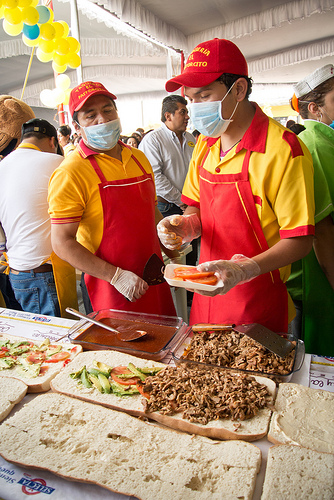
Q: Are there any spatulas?
A: Yes, there is a spatula.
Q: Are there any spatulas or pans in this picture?
A: Yes, there is a spatula.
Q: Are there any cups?
A: No, there are no cups.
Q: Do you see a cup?
A: No, there are no cups.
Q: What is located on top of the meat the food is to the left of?
A: The spatula is on top of the meat.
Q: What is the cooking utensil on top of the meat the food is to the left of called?
A: The cooking utensil is a spatula.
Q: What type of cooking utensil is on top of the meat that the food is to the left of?
A: The cooking utensil is a spatula.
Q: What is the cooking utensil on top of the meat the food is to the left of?
A: The cooking utensil is a spatula.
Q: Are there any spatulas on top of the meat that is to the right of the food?
A: Yes, there is a spatula on top of the meat.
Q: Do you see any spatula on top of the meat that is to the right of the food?
A: Yes, there is a spatula on top of the meat.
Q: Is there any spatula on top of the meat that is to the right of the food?
A: Yes, there is a spatula on top of the meat.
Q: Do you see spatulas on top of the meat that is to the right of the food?
A: Yes, there is a spatula on top of the meat.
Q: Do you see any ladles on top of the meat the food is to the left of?
A: No, there is a spatula on top of the meat.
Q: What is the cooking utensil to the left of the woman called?
A: The cooking utensil is a spatula.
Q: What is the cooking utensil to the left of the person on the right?
A: The cooking utensil is a spatula.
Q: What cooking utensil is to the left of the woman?
A: The cooking utensil is a spatula.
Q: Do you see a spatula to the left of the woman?
A: Yes, there is a spatula to the left of the woman.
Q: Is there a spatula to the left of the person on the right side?
A: Yes, there is a spatula to the left of the woman.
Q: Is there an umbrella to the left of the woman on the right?
A: No, there is a spatula to the left of the woman.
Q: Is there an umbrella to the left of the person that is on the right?
A: No, there is a spatula to the left of the woman.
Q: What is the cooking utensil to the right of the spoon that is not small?
A: The cooking utensil is a spatula.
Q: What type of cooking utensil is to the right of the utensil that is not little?
A: The cooking utensil is a spatula.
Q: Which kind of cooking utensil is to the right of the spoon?
A: The cooking utensil is a spatula.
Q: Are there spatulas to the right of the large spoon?
A: Yes, there is a spatula to the right of the spoon.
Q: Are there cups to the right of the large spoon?
A: No, there is a spatula to the right of the spoon.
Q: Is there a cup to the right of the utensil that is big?
A: No, there is a spatula to the right of the spoon.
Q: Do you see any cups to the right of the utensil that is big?
A: No, there is a spatula to the right of the spoon.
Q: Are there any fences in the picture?
A: No, there are no fences.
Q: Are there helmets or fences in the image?
A: No, there are no fences or helmets.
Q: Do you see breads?
A: Yes, there is a bread.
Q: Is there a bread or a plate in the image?
A: Yes, there is a bread.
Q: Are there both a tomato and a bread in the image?
A: Yes, there are both a bread and a tomato.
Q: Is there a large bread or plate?
A: Yes, there is a large bread.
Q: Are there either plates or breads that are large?
A: Yes, the bread is large.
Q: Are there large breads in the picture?
A: Yes, there is a large bread.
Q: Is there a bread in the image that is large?
A: Yes, there is a bread that is large.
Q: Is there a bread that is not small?
A: Yes, there is a large bread.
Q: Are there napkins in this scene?
A: No, there are no napkins.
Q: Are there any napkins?
A: No, there are no napkins.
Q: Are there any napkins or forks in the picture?
A: No, there are no napkins or forks.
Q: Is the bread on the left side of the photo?
A: Yes, the bread is on the left of the image.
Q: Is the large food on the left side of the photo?
A: Yes, the bread is on the left of the image.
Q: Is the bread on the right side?
A: No, the bread is on the left of the image.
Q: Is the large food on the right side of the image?
A: No, the bread is on the left of the image.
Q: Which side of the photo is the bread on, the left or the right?
A: The bread is on the left of the image.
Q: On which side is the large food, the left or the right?
A: The bread is on the left of the image.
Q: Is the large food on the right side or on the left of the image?
A: The bread is on the left of the image.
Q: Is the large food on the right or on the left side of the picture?
A: The bread is on the left of the image.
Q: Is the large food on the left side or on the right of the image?
A: The bread is on the left of the image.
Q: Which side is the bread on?
A: The bread is on the left of the image.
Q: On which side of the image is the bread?
A: The bread is on the left of the image.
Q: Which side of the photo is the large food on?
A: The bread is on the left of the image.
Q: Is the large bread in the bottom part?
A: Yes, the bread is in the bottom of the image.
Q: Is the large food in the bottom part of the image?
A: Yes, the bread is in the bottom of the image.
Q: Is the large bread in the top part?
A: No, the bread is in the bottom of the image.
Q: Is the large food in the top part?
A: No, the bread is in the bottom of the image.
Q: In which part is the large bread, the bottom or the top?
A: The bread is in the bottom of the image.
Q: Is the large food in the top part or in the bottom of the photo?
A: The bread is in the bottom of the image.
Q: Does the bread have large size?
A: Yes, the bread is large.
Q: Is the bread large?
A: Yes, the bread is large.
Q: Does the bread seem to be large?
A: Yes, the bread is large.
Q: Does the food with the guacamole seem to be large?
A: Yes, the bread is large.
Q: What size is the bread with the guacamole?
A: The bread is large.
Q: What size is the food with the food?
A: The bread is large.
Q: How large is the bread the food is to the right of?
A: The bread is large.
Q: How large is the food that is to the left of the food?
A: The bread is large.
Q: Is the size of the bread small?
A: No, the bread is large.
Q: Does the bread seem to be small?
A: No, the bread is large.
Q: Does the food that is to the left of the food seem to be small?
A: No, the bread is large.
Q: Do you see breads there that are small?
A: No, there is a bread but it is large.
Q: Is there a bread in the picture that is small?
A: No, there is a bread but it is large.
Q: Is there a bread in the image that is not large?
A: No, there is a bread but it is large.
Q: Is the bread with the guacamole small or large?
A: The bread is large.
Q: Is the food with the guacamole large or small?
A: The bread is large.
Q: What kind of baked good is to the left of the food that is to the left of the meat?
A: The food is a bread.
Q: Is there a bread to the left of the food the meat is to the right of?
A: Yes, there is a bread to the left of the food.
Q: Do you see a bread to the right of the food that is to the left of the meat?
A: No, the bread is to the left of the food.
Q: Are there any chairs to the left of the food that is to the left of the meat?
A: No, there is a bread to the left of the food.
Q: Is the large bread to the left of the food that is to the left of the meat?
A: Yes, the bread is to the left of the food.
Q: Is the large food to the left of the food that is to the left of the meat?
A: Yes, the bread is to the left of the food.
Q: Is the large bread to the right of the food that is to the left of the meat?
A: No, the bread is to the left of the food.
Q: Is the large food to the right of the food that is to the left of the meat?
A: No, the bread is to the left of the food.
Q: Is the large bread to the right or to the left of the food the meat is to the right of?
A: The bread is to the left of the food.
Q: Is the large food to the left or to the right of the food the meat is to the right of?
A: The bread is to the left of the food.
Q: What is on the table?
A: The bread is on the table.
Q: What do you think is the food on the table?
A: The food is a bread.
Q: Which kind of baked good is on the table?
A: The food is a bread.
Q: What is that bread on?
A: The bread is on the table.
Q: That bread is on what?
A: The bread is on the table.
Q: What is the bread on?
A: The bread is on the table.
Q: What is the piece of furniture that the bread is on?
A: The piece of furniture is a table.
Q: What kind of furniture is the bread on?
A: The bread is on the table.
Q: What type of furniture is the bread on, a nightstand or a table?
A: The bread is on a table.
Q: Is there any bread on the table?
A: Yes, there is a bread on the table.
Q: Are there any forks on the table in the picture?
A: No, there is a bread on the table.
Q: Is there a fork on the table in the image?
A: No, there is a bread on the table.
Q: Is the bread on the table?
A: Yes, the bread is on the table.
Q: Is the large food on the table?
A: Yes, the bread is on the table.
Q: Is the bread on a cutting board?
A: No, the bread is on the table.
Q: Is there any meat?
A: Yes, there is meat.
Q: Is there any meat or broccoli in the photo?
A: Yes, there is meat.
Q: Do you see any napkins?
A: No, there are no napkins.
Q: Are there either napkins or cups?
A: No, there are no napkins or cups.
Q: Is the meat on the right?
A: Yes, the meat is on the right of the image.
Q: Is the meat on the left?
A: No, the meat is on the right of the image.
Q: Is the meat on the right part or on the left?
A: The meat is on the right of the image.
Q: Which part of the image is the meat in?
A: The meat is on the right of the image.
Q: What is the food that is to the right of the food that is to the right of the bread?
A: The food is meat.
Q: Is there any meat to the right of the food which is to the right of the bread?
A: Yes, there is meat to the right of the food.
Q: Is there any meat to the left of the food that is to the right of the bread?
A: No, the meat is to the right of the food.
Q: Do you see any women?
A: Yes, there is a woman.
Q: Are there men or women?
A: Yes, there is a woman.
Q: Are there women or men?
A: Yes, there is a woman.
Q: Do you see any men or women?
A: Yes, there is a woman.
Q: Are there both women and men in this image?
A: Yes, there are both a woman and a man.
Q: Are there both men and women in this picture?
A: Yes, there are both a woman and a man.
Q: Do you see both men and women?
A: Yes, there are both a woman and a man.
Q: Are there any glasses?
A: No, there are no glasses.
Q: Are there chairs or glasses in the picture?
A: No, there are no glasses or chairs.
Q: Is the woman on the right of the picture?
A: Yes, the woman is on the right of the image.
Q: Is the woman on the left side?
A: No, the woman is on the right of the image.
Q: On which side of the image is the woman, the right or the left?
A: The woman is on the right of the image.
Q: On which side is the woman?
A: The woman is on the right of the image.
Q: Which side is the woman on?
A: The woman is on the right of the image.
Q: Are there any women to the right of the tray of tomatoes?
A: Yes, there is a woman to the right of the tray.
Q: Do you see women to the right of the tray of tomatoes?
A: Yes, there is a woman to the right of the tray.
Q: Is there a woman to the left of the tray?
A: No, the woman is to the right of the tray.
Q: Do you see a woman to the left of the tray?
A: No, the woman is to the right of the tray.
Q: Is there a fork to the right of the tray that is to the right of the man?
A: No, there is a woman to the right of the tray.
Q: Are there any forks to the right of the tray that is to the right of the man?
A: No, there is a woman to the right of the tray.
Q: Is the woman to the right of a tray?
A: Yes, the woman is to the right of a tray.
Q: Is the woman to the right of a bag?
A: No, the woman is to the right of a tray.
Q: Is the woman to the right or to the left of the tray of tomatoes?
A: The woman is to the right of the tray.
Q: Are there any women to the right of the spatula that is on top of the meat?
A: Yes, there is a woman to the right of the spatula.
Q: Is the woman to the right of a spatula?
A: Yes, the woman is to the right of a spatula.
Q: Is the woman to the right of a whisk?
A: No, the woman is to the right of a spatula.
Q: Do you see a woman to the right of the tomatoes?
A: Yes, there is a woman to the right of the tomatoes.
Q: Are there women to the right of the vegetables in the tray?
A: Yes, there is a woman to the right of the tomatoes.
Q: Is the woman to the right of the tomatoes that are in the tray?
A: Yes, the woman is to the right of the tomatoes.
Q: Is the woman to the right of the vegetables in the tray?
A: Yes, the woman is to the right of the tomatoes.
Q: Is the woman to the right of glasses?
A: No, the woman is to the right of the tomatoes.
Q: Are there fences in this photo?
A: No, there are no fences.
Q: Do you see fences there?
A: No, there are no fences.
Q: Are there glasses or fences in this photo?
A: No, there are no fences or glasses.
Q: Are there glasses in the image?
A: No, there are no glasses.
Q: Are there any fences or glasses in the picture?
A: No, there are no glasses or fences.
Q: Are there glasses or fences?
A: No, there are no glasses or fences.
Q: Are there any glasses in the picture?
A: No, there are no glasses.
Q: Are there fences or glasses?
A: No, there are no glasses or fences.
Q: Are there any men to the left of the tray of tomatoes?
A: Yes, there is a man to the left of the tray.